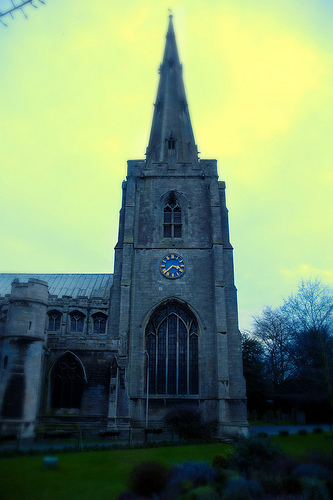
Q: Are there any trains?
A: No, there are no trains.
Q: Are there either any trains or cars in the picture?
A: No, there are no trains or cars.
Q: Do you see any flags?
A: No, there are no flags.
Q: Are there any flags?
A: No, there are no flags.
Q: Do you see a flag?
A: No, there are no flags.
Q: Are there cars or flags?
A: No, there are no flags or cars.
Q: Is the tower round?
A: Yes, the tower is round.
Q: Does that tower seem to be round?
A: Yes, the tower is round.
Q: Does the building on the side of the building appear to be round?
A: Yes, the tower is round.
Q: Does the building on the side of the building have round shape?
A: Yes, the tower is round.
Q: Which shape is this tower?
A: The tower is round.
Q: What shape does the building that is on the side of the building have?
A: The tower has round shape.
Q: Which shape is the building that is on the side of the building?
A: The tower is round.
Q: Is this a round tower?
A: Yes, this is a round tower.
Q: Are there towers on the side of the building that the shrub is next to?
A: Yes, there is a tower on the side of the building.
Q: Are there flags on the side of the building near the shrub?
A: No, there is a tower on the side of the building.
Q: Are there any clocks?
A: Yes, there is a clock.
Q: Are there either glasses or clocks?
A: Yes, there is a clock.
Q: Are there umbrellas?
A: No, there are no umbrellas.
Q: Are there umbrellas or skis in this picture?
A: No, there are no umbrellas or skis.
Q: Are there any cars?
A: No, there are no cars.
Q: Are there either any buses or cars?
A: No, there are no cars or buses.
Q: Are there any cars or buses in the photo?
A: No, there are no cars or buses.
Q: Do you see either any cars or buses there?
A: No, there are no cars or buses.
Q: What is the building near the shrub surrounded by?
A: The building is surrounded by the gate.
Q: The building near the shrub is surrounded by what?
A: The building is surrounded by the gate.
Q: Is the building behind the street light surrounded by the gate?
A: Yes, the building is surrounded by the gate.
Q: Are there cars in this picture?
A: No, there are no cars.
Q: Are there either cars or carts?
A: No, there are no cars or carts.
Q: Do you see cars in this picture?
A: No, there are no cars.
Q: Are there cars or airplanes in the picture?
A: No, there are no cars or airplanes.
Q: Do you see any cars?
A: No, there are no cars.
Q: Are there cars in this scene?
A: No, there are no cars.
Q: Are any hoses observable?
A: No, there are no hoses.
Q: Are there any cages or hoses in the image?
A: No, there are no hoses or cages.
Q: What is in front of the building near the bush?
A: The street lamp is in front of the building.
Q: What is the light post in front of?
A: The light post is in front of the building.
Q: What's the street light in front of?
A: The light post is in front of the building.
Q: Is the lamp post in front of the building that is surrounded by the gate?
A: Yes, the lamp post is in front of the building.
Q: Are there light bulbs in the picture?
A: No, there are no light bulbs.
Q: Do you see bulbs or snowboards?
A: No, there are no bulbs or snowboards.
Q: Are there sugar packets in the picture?
A: No, there are no sugar packets.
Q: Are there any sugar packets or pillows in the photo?
A: No, there are no sugar packets or pillows.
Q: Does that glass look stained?
A: Yes, the glass is stained.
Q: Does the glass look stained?
A: Yes, the glass is stained.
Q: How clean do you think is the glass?
A: The glass is stained.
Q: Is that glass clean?
A: No, the glass is stained.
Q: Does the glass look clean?
A: No, the glass is stained.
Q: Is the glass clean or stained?
A: The glass is stained.